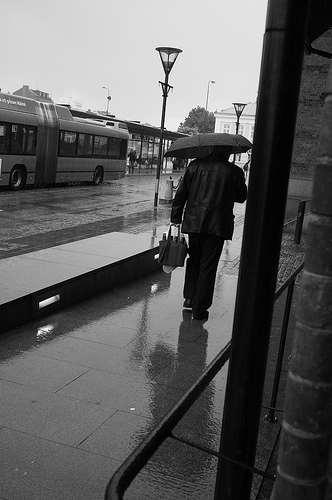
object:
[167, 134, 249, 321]
man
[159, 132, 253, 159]
umbrella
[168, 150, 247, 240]
jacket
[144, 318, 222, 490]
shadow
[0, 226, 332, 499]
street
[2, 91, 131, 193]
bus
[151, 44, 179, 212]
pole